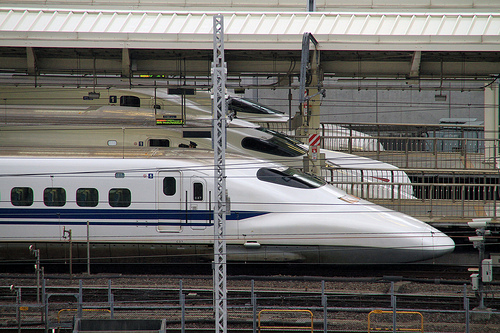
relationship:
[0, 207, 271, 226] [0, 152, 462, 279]
line painted on train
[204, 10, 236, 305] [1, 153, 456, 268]
pole standing in front of bullet train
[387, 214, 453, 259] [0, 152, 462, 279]
tip belonging to train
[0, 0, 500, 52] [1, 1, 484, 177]
roof covering building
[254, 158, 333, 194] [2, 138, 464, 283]
windshield built into train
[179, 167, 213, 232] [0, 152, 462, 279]
door leading to train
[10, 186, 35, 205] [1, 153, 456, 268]
window built into bullet train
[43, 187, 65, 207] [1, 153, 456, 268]
window built into bullet train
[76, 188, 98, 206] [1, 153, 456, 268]
window built into bullet train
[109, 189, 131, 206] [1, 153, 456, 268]
window built into bullet train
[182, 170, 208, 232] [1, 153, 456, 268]
door leading to bullet train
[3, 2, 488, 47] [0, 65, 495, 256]
roof of train station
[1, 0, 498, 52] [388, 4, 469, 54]
tiles on roof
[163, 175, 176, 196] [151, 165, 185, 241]
window in door